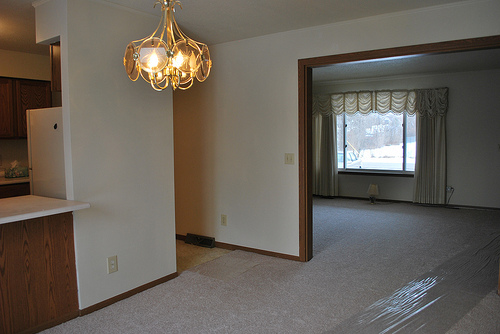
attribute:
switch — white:
[283, 150, 300, 170]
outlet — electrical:
[101, 250, 121, 282]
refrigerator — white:
[20, 99, 81, 214]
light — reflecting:
[111, 20, 210, 94]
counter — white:
[0, 184, 90, 229]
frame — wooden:
[0, 187, 90, 330]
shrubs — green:
[343, 142, 365, 162]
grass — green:
[338, 141, 414, 168]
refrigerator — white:
[26, 106, 64, 194]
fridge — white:
[25, 104, 67, 199]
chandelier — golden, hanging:
[119, 30, 214, 92]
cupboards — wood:
[0, 76, 55, 135]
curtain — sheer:
[309, 85, 449, 202]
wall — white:
[310, 65, 497, 210]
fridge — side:
[24, 104, 71, 198]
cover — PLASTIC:
[321, 214, 498, 332]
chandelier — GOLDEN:
[124, 2, 212, 89]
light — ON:
[149, 47, 163, 65]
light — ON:
[173, 49, 185, 69]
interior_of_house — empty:
[1, 1, 469, 327]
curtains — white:
[310, 86, 448, 208]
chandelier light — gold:
[117, 0, 216, 97]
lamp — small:
[122, 1, 213, 91]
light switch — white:
[269, 147, 304, 175]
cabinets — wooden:
[2, 73, 63, 148]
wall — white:
[228, 85, 282, 150]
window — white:
[341, 90, 473, 170]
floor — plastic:
[366, 242, 498, 327]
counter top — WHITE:
[0, 190, 105, 222]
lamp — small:
[361, 182, 383, 205]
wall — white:
[171, 0, 498, 262]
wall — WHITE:
[72, 56, 161, 305]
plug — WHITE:
[97, 244, 119, 272]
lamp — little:
[364, 180, 385, 204]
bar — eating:
[1, 184, 91, 332]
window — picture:
[334, 98, 421, 174]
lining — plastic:
[334, 214, 494, 332]